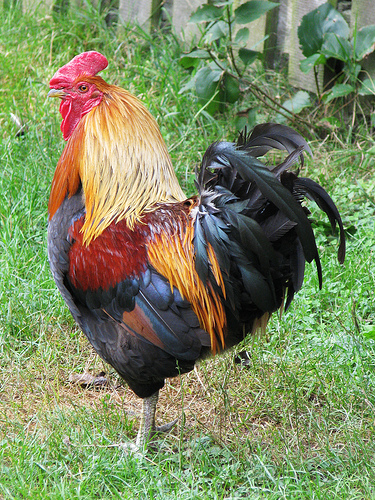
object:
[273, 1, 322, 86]
wood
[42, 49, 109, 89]
red crest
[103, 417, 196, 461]
feet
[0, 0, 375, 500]
grass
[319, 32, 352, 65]
leaf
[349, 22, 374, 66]
leaf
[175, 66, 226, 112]
leaf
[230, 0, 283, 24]
leaf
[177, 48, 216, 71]
leaf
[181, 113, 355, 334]
tail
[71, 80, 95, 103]
eye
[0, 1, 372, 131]
fence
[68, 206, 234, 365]
wings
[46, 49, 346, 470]
bird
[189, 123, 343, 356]
feather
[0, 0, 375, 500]
field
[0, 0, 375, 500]
yard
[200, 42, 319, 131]
branch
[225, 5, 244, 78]
branch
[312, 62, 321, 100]
branch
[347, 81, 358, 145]
branch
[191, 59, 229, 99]
leaf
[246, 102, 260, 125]
leaf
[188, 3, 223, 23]
leaf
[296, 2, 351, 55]
leaf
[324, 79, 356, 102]
leaf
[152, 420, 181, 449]
talon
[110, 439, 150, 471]
talon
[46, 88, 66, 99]
beak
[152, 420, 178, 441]
foot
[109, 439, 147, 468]
foot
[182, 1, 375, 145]
plant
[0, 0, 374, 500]
background